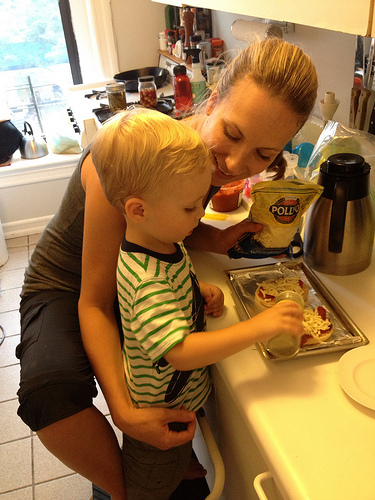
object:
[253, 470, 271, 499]
handle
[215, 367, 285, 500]
cabinet drawer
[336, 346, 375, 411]
plate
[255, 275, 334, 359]
food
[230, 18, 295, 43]
rack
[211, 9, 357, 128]
wall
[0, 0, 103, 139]
window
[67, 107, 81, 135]
control knobs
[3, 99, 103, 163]
stove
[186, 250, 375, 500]
counter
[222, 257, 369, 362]
baking sheet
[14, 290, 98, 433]
shorts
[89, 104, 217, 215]
hair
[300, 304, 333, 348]
pizza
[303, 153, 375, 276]
coffee pot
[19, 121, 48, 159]
coffee pot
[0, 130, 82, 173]
counter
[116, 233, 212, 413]
shirt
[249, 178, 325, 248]
bag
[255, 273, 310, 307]
pizzas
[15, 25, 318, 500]
mom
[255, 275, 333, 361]
cook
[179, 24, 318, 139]
hair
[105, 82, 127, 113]
food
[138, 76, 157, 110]
food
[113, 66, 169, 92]
pan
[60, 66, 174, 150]
stove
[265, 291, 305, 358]
cheese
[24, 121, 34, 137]
handle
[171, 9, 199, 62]
pepper grinder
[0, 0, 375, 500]
kitchen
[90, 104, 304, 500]
boy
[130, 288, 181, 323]
stripes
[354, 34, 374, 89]
knives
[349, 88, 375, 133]
handles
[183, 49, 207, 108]
spray bottle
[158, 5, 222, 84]
spices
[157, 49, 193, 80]
shelf